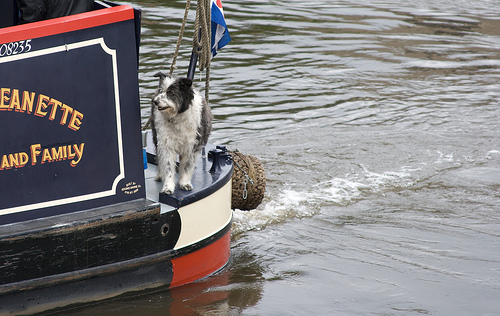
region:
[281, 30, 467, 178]
The water is still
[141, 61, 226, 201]
The dog is on the boat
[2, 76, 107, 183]
Words on the boat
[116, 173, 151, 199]
The boat's logo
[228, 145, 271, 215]
A tire on the back of the boat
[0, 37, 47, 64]
These are white letters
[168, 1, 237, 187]
Flag on the boat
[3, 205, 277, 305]
Boat is orange and blue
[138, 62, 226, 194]
Dog is black and white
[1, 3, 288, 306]
Boat is moving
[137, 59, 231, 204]
a dog on the boat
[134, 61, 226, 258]
a dog on the boat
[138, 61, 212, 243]
a dog on the boat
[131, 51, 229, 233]
a dog on the boat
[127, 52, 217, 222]
a dog on the boat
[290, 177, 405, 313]
the water is murky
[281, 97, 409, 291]
the water is murky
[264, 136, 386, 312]
the water is murky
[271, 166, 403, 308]
the water is murky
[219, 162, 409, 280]
the water is murky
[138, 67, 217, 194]
dog on the boat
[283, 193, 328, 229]
wave in the water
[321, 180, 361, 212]
wave in the water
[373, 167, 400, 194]
wave in the water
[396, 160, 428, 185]
wave in the water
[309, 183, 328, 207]
wave in the water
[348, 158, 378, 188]
wave in the water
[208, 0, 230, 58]
red, white, and blue flag on back of boat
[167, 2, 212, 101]
brown rope hanging from boat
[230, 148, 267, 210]
brown object on back of boat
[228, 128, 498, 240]
wake from boat motor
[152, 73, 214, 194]
black and white dog standing on boat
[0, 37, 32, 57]
white identification number on boat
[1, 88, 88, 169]
yellow lettering on side of boat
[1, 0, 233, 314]
red, black, and white boat in the water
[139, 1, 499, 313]
riples in the water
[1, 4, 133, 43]
red stripe on side of boat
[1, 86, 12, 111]
The letter is yellow and outlined in orange.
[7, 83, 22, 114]
The letter is yellow and outlined in orange.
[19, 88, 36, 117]
The letter is yellow and outlined in orange.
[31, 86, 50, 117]
The letter is yellow and outlined in orange.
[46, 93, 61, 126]
The letter is yellow and outlined in orange.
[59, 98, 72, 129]
The letter is yellow and outlined in orange.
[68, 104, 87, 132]
The letter is yellow and outlined in orange.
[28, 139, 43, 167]
The letter is yellow and outlined in orange.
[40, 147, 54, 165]
The letter is yellow and outlined in orange.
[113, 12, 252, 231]
A black and white dog standing on about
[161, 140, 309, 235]
A basket at the end of the boat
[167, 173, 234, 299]
A red and white front of the boat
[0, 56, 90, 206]
Writing on the side of the boat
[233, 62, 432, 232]
Ripples in the water from the boat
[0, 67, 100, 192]
Gold writing on the side of the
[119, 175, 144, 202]
Small writing and why on the bottom of the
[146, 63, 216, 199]
Grey and white scruffy dog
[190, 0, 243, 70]
Red, white, and blue flag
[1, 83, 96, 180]
Yellow writing on the blue boat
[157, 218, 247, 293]
Red colored bottom of the boat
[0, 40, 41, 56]
White numbers on a blue boat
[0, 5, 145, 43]
Red trim on a blue boat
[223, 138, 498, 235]
Bubbley wake of the boat